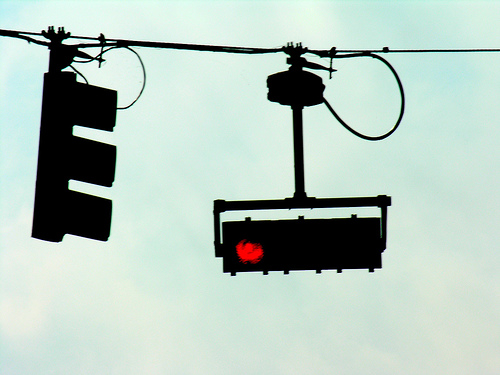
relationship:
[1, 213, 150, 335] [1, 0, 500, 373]
cloud in middle of sky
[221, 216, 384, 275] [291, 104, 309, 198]
traffic light on end of pole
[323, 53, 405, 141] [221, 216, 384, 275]
lines to traffic light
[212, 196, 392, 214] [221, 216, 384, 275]
base on top of traffic light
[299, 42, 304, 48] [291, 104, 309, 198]
screw on top of pole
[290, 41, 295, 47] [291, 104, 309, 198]
screw on top of pole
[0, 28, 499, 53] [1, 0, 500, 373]
electrical line in middle of sky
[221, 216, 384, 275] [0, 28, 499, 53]
traffic light hanging from electrical line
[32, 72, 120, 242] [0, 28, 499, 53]
traffic light hanging from electrical line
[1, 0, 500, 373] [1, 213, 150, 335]
sky has cloud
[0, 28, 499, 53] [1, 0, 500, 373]
electrical line running across sky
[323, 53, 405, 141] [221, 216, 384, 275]
lines running to traffic light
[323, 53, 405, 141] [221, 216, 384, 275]
lines connecting to traffic light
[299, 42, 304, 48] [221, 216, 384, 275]
screw attaching traffic light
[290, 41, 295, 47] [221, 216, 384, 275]
screw attaching traffic light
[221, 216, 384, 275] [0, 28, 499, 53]
traffic light attached to electrical line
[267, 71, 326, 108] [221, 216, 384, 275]
rotating piece on top of traffic light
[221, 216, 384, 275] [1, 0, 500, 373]
traffic light hanging in sky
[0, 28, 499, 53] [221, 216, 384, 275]
electrical line holding traffic light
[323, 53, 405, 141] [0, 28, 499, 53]
lines hanging from electrical line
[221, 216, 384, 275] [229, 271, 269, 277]
traffic light has slot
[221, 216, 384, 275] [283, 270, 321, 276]
traffic light has slot